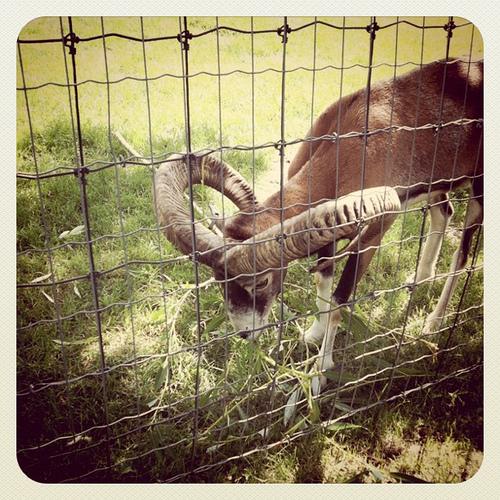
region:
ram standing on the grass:
[135, 37, 450, 427]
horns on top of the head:
[122, 135, 402, 305]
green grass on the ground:
[17, 16, 478, 489]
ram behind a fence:
[110, 58, 498, 429]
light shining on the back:
[453, 55, 480, 80]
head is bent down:
[153, 130, 408, 368]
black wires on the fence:
[16, 15, 473, 487]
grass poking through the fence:
[281, 365, 327, 406]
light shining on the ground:
[306, 427, 477, 481]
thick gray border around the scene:
[1, 1, 499, 496]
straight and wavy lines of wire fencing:
[32, 30, 468, 465]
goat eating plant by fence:
[145, 241, 315, 406]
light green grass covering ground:
[26, 26, 471, 476]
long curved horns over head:
[151, 140, 396, 310]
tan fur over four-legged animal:
[157, 50, 477, 390]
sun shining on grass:
[30, 31, 350, 127]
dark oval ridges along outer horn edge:
[295, 195, 385, 247]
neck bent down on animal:
[137, 92, 374, 332]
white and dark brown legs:
[300, 192, 475, 372]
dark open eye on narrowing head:
[212, 267, 287, 342]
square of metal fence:
[26, 83, 81, 175]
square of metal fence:
[63, 375, 114, 435]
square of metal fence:
[136, 356, 171, 415]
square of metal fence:
[166, 353, 197, 410]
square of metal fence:
[200, 340, 222, 411]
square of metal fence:
[221, 338, 255, 405]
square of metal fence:
[93, 270, 132, 307]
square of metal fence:
[193, 253, 228, 286]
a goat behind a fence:
[148, 86, 499, 483]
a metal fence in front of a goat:
[161, 64, 426, 372]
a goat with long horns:
[123, 101, 490, 350]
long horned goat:
[152, 78, 387, 397]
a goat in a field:
[89, 128, 447, 403]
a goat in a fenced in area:
[79, 77, 433, 427]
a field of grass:
[42, 109, 432, 489]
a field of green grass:
[14, 116, 496, 434]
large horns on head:
[158, 147, 394, 277]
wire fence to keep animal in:
[25, 88, 499, 429]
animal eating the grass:
[183, 240, 288, 348]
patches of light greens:
[382, 440, 491, 487]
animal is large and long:
[146, 56, 487, 368]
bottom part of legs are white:
[398, 213, 471, 328]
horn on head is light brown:
[223, 191, 399, 250]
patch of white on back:
[455, 54, 484, 101]